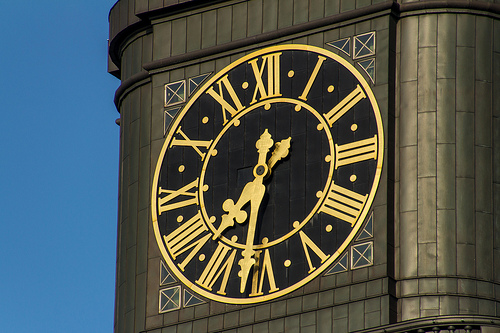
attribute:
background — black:
[168, 74, 406, 313]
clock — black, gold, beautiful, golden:
[148, 42, 385, 305]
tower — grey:
[108, 1, 499, 332]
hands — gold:
[213, 128, 291, 293]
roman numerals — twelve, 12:
[248, 52, 284, 105]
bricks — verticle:
[396, 13, 499, 320]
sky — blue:
[0, 0, 120, 333]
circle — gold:
[230, 233, 239, 242]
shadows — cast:
[110, 0, 226, 78]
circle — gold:
[197, 96, 336, 250]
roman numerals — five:
[296, 228, 330, 274]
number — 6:
[248, 248, 280, 297]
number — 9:
[156, 178, 200, 215]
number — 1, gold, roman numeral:
[297, 54, 326, 102]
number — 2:
[319, 83, 367, 128]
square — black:
[164, 80, 187, 107]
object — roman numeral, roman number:
[206, 74, 247, 124]